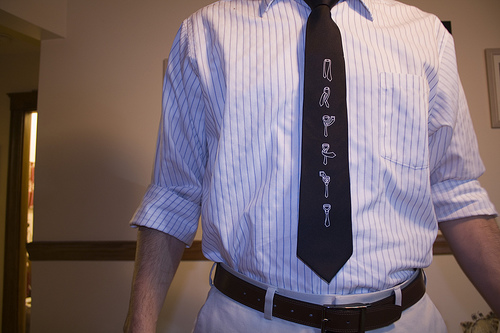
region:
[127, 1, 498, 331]
A man standing upright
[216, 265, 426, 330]
A dark colored belt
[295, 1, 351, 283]
A black tie with a tie design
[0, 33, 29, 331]
A slightly open wooden door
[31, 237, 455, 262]
Dark colored trim on a wall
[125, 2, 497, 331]
A man standing wearing a short sleeved shirt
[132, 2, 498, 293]
A white shirt with blsck virtical strips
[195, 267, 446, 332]
A tan pair of slacks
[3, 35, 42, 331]
A open door showing part of the next room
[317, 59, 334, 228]
Illustrations of a tie being tied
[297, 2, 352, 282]
TIE IS BLACK IN COLOR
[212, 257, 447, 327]
BELT IS BROWN IN COLOR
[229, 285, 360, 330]
BELT HAS SEVEN HOLES IN IT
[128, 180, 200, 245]
PERSON HAS SLEEVE ROLLED UP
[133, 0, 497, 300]
SHIRT IS WHITE WITH PIN STRIPES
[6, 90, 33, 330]
DOORWAY TO OTHER ROOM IS TO THE LEFT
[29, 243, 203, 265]
BROWN CHAIR RAIL IN ON BACK WALL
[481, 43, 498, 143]
PICTURE HANGING ON BACK WALL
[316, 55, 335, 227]
PICTURES ON TIE SHOW HOW TO TIE A TIE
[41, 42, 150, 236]
BACK WALL IS WHITE IN COLOR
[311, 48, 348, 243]
The white design on the man's tie.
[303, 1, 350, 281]
The black tie the man is wearing.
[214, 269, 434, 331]
The belt the man is wearing.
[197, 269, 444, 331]
The pants the man is wearing.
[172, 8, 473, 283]
The stripe shirt the man is wearing.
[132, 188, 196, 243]
The rolled up sleeve on the left.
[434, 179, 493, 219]
The rolled up sleeve on the right.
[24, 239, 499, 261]
The brown border molding on the wall behind the man.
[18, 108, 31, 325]
The doorway on the left.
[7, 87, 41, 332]
The brown door frame on the left.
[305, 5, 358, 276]
black tie with images on it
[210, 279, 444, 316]
black belt around man's waist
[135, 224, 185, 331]
arm with hair on it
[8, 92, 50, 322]
opening to a bathroom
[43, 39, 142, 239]
wall painted with white paint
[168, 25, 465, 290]
man shirt with stripes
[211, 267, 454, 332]
man wearing khaki pants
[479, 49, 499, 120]
painting hanging on the wall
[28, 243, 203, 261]
wood panel on wall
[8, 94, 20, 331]
wood paneling around door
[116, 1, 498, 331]
a man is standing in the room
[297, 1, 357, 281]
the mans tie has drawings on it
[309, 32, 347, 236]
each drawing on the tie show how to tie the tie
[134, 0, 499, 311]
the mans shirt is blue and white striped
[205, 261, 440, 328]
the man is wearing a black belt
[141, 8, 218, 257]
the mans sleaves are rolled up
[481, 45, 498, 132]
a picture hangs on the wall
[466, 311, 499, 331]
a throw pillow is on a chair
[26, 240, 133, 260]
brown trim is dividing the wall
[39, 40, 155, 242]
the wall is tan on top